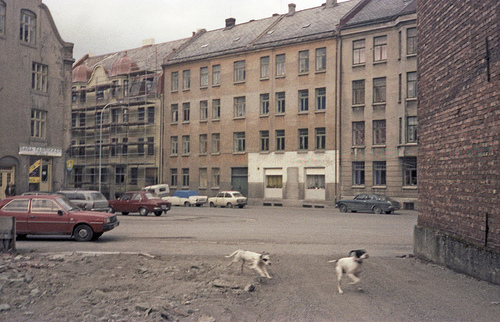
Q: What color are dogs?
A: White and black.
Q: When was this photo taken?
A: Daytime.